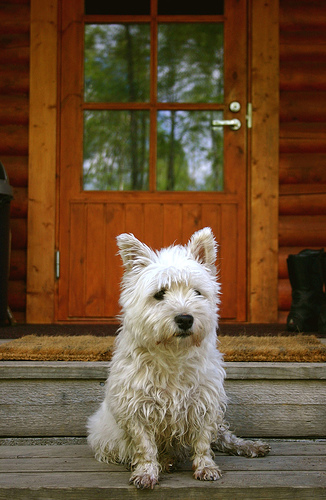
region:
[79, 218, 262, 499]
small dog sitting down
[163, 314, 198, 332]
small black nose of dog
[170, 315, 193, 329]
tiny black nose of dog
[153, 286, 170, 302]
black eye of dog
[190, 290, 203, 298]
small black eye of dog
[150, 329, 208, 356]
brown fur on end of face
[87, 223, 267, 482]
white furry dog sitting down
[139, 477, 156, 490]
small orange claws on paws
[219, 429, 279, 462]
back leg of dog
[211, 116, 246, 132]
silver handle on door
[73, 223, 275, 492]
A dog waiting in front of a door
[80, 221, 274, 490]
A dog waiting in front of a door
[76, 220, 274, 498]
A dog waiting in front of a door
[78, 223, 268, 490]
A dog waiting in front of a door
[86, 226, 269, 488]
White dog sitting on the porch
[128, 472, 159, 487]
Pink showing through dog's paw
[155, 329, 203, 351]
Brown fur on dog's face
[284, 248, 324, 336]
Black boots on porch next to door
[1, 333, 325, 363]
Brown mat laying behind dog on porch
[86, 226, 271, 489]
Dog waiting alone on porch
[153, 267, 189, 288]
Fur hanging over dog's eyes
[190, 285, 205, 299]
Left eye of dog hidden in fur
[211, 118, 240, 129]
Metal handle on the door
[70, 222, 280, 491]
A dog sitting in front of an entrance door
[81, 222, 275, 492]
A dog sitting in front of an entrance door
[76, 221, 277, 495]
A dog sitting in front of an entrance door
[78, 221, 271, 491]
A dog sitting in front of an entrance door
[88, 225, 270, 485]
White dog sitting on porch.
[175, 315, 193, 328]
White dog has black nose.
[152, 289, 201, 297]
White dog has black eyes.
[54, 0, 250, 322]
House has wooden door.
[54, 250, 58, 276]
Silver hinge on front door.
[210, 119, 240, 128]
Silver door handle on door.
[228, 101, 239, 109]
Deadbolt lock on door.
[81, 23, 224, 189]
Trees reflecting in bottom window panes.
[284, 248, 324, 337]
Black boots sitting on porch.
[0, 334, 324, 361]
Brown door mat sitting on porch.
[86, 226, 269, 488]
A white dog sitting on stairs.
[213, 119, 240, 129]
A silver door handle on a wooden door.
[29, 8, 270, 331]
wood door to home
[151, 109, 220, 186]
window on door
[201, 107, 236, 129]
handle on door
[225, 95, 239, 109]
lock on door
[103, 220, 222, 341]
head of the dog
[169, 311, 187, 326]
nose of the dog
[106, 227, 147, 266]
right ear of the dog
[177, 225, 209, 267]
left ear of the dog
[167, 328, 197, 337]
mouth of the dog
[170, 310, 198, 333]
the nose is black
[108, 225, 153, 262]
the ear is white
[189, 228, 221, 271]
ear is white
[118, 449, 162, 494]
dog has a white paw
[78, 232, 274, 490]
the dog is white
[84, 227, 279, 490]
the dog is fluffy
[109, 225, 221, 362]
the dog has a white head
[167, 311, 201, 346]
a black nose on a white dog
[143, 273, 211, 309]
black eyes on a white dog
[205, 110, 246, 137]
the handle is gold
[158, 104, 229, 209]
A window on a building.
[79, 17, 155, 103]
A window on a building.